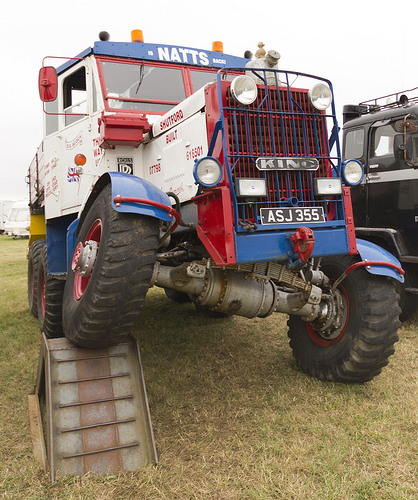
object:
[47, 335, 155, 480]
ramp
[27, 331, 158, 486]
jack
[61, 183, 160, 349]
tire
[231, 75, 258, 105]
headlight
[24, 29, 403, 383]
truck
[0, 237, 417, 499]
grass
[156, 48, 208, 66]
writing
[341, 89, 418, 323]
car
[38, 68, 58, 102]
side mirror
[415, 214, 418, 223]
writing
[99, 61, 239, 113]
windshield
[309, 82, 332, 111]
headlight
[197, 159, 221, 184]
headlight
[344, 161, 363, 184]
headlight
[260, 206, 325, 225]
license plate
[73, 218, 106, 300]
wheel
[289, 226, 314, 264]
clamp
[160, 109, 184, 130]
sticker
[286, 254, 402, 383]
tire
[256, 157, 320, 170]
sign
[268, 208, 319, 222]
letters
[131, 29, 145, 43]
lights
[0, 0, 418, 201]
sky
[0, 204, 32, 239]
trailers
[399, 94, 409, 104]
horn